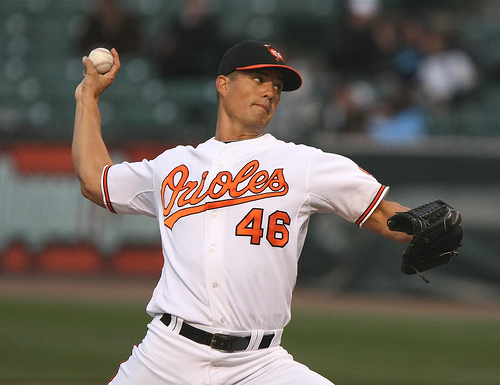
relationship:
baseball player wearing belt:
[72, 40, 464, 385] [161, 313, 273, 351]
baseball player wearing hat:
[72, 40, 464, 385] [214, 41, 301, 89]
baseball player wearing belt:
[72, 40, 464, 385] [157, 314, 282, 351]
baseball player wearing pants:
[72, 40, 464, 385] [97, 282, 298, 382]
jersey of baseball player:
[108, 140, 358, 381] [72, 40, 464, 385]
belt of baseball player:
[160, 313, 275, 353] [72, 40, 464, 385]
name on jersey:
[136, 153, 399, 234] [101, 132, 389, 332]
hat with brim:
[208, 39, 303, 97] [239, 60, 306, 90]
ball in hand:
[88, 47, 113, 75] [71, 46, 127, 100]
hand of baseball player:
[71, 46, 127, 100] [72, 40, 464, 385]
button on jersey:
[213, 282, 218, 287] [100, 132, 388, 330]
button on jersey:
[220, 317, 225, 322] [100, 132, 388, 330]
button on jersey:
[208, 243, 217, 251] [100, 132, 388, 330]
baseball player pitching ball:
[72, 40, 464, 385] [80, 40, 116, 78]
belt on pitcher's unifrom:
[160, 309, 295, 351] [101, 131, 393, 382]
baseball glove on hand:
[386, 198, 464, 282] [400, 198, 467, 255]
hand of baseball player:
[400, 198, 467, 255] [72, 40, 464, 385]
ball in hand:
[88, 47, 113, 75] [78, 39, 124, 94]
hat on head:
[215, 39, 300, 92] [197, 44, 277, 129]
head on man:
[197, 44, 277, 129] [64, 32, 378, 382]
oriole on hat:
[268, 41, 286, 71] [212, 37, 304, 94]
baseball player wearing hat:
[72, 40, 464, 385] [212, 37, 304, 94]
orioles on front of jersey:
[157, 157, 302, 227] [101, 132, 389, 332]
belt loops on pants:
[168, 315, 188, 333] [105, 315, 337, 384]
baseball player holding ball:
[72, 40, 464, 385] [88, 47, 113, 75]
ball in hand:
[88, 47, 113, 75] [74, 47, 121, 99]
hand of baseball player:
[74, 47, 121, 99] [72, 40, 464, 385]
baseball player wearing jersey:
[60, 33, 469, 383] [93, 139, 407, 343]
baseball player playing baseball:
[72, 40, 464, 385] [53, 24, 422, 382]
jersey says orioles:
[101, 132, 389, 332] [150, 155, 295, 227]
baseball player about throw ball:
[72, 40, 464, 385] [83, 45, 113, 75]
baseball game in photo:
[6, 5, 498, 385] [1, 4, 493, 378]